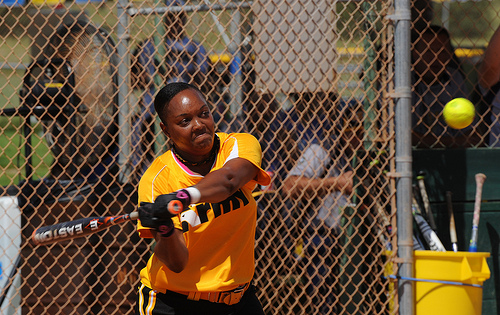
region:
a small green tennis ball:
[441, 93, 473, 129]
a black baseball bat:
[30, 195, 183, 245]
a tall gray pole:
[385, 1, 425, 311]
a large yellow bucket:
[375, 241, 490, 311]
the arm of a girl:
[185, 127, 270, 192]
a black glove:
[145, 190, 195, 215]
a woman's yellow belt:
[174, 288, 249, 305]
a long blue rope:
[387, 267, 480, 288]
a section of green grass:
[2, 123, 47, 183]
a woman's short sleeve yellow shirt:
[135, 132, 275, 289]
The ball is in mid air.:
[412, 87, 492, 139]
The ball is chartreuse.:
[430, 88, 478, 137]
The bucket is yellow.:
[382, 170, 497, 313]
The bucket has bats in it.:
[386, 146, 496, 311]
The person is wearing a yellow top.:
[94, 114, 288, 302]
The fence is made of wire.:
[282, 0, 410, 314]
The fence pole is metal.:
[383, 0, 425, 314]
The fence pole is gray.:
[380, 0, 424, 313]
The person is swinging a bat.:
[17, 182, 197, 263]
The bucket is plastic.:
[367, 207, 494, 314]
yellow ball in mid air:
[429, 83, 479, 140]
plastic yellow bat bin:
[408, 221, 497, 313]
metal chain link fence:
[2, 3, 424, 313]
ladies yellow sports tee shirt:
[130, 128, 272, 307]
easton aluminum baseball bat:
[32, 195, 181, 250]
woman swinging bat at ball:
[135, 77, 280, 312]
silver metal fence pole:
[377, 3, 425, 313]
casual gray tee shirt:
[290, 122, 362, 262]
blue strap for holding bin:
[387, 262, 486, 314]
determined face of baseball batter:
[166, 95, 225, 157]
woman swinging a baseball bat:
[25, 71, 301, 311]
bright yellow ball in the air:
[427, 84, 482, 141]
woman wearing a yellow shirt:
[97, 90, 312, 297]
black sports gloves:
[131, 188, 193, 236]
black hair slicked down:
[133, 67, 227, 167]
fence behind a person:
[16, 17, 433, 297]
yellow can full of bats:
[360, 162, 495, 312]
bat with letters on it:
[31, 213, 139, 244]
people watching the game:
[141, 29, 473, 293]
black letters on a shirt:
[168, 174, 243, 228]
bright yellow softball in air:
[435, 93, 481, 133]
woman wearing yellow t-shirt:
[112, 66, 274, 301]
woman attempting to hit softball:
[12, 75, 498, 296]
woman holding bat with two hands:
[18, 65, 330, 313]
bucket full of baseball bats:
[379, 165, 492, 313]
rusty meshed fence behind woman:
[6, 4, 392, 304]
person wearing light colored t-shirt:
[284, 93, 371, 248]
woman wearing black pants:
[44, 80, 310, 314]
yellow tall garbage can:
[364, 218, 499, 313]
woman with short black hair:
[121, 70, 268, 187]